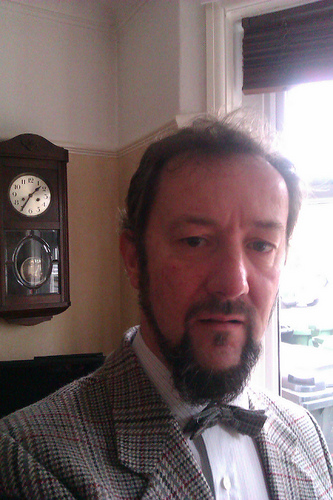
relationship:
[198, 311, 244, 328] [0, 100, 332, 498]
mouth on man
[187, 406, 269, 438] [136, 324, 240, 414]
bow tie on mans neck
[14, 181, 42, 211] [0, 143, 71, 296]
face on clock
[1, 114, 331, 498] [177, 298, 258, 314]
guy has mustache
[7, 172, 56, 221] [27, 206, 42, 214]
clock has numbers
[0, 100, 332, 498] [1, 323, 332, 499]
man wearing suit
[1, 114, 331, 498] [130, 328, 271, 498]
guy wearing collared shirt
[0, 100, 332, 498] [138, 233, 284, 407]
man with beard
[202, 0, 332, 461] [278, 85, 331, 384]
window showing sunlight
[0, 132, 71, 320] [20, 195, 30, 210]
clock has hands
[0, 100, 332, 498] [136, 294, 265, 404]
man has facial hair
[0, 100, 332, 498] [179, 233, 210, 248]
man has eye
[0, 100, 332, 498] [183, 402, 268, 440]
man wearing bow tie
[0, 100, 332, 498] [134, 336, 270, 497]
man wearing shirt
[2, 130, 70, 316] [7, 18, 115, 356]
wood clock to wall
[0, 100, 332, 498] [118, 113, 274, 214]
man has hair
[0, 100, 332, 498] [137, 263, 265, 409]
man has beard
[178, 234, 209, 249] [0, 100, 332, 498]
eye of man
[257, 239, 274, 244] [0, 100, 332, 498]
eye lash of man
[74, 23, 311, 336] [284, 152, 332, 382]
scene happening day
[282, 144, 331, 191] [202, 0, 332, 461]
sun shining through window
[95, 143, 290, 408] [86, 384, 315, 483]
guy wearing jacket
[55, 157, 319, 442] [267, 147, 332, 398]
guy near window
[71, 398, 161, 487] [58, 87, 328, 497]
jacket worn by man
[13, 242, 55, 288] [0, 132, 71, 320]
pendulum inside clock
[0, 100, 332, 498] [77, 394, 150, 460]
man wearing jacket